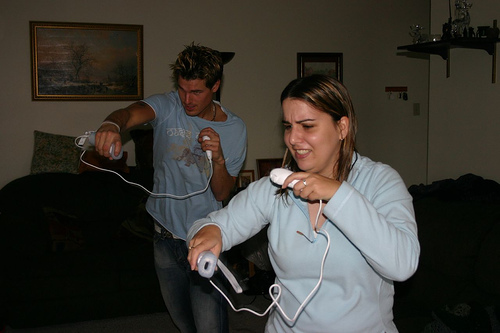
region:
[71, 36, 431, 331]
guy and girl playing a video game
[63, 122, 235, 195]
guy holding the controller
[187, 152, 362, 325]
girl holding the controller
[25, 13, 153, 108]
scenery painting hung on the wall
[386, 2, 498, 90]
things kept in the distance on a shelf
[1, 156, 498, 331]
couches to sit on in the room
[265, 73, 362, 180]
girl giving a annoyed expression on her face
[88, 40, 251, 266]
guy wearing a blue t shirt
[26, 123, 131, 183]
pillow at the back of the sofa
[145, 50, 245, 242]
man playing video games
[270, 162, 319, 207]
wii remote in girl's hands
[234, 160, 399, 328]
blue sweater on girl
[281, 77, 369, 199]
long blonde hair on girl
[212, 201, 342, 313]
white wire of wii remote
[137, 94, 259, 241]
blue shirt on man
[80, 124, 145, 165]
wii remote in man's hand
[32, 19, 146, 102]
painting hanging on wall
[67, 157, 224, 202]
white wire of wii remote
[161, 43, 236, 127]
spiky hair on a man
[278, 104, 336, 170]
grimace on a woman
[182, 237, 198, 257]
gold ring on a finger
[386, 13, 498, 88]
shelf mounted on the wall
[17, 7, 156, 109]
painting over a couch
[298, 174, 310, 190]
silver ring on a woman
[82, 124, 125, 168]
Wii mote in a hand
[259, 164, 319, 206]
woman holding a Wii mote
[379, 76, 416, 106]
key holder on the wall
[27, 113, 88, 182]
pillow on the couch back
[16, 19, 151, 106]
The picture on the wall.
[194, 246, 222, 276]
The game controller in the woman's hand.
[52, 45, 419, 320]
A man and a woman playing a game.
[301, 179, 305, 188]
Silver ring on the woman's finger.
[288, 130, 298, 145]
The woman's nose.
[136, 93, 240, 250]
The blue tee shirt.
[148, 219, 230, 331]
The mans blue jeans.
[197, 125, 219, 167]
The game controller in the man's hand.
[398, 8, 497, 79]
The shelf on the wall.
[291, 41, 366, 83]
The small picture on the wall.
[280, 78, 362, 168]
A girl with brown hair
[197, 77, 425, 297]
A girl playing a game using remotes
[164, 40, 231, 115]
A man with brown hair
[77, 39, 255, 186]
A man playing a game with remotes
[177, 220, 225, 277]
A hand holding a remote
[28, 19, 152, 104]
A picture hanging on a wall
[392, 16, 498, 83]
A shelf hanging on a wall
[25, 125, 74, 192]
A pillow on a couch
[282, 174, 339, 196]
A ring on a finger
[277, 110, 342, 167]
A girl with a facial expression